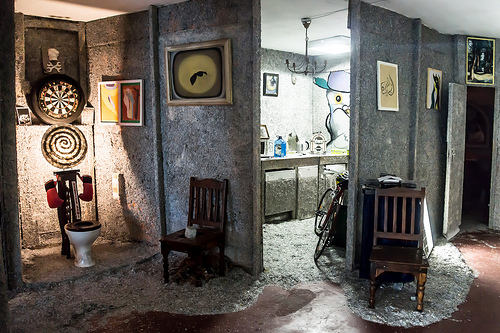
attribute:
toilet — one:
[45, 191, 133, 276]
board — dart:
[35, 77, 85, 124]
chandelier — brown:
[281, 17, 338, 75]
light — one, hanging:
[267, 20, 349, 81]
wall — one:
[363, 125, 398, 177]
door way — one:
[225, 16, 389, 271]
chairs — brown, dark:
[157, 177, 452, 313]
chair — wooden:
[153, 173, 241, 287]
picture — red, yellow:
[10, 7, 495, 310]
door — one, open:
[428, 71, 499, 233]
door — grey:
[257, 46, 364, 288]